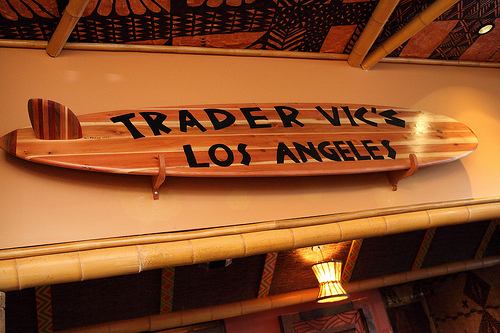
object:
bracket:
[386, 153, 417, 190]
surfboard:
[0, 96, 480, 179]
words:
[271, 139, 396, 167]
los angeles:
[181, 140, 403, 168]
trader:
[94, 90, 311, 140]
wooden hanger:
[148, 152, 167, 201]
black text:
[108, 105, 407, 139]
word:
[182, 141, 251, 169]